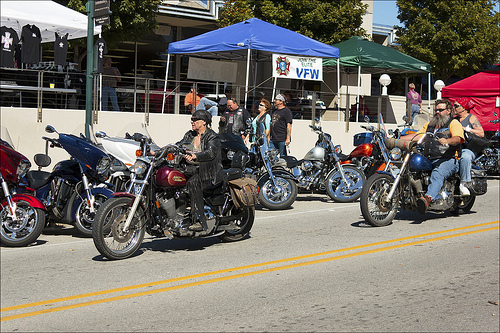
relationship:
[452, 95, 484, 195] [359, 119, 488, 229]
man on bike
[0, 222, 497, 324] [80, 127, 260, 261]
line on bike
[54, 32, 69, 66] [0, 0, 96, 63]
shirt hanging tent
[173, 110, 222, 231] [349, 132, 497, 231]
guy riding bike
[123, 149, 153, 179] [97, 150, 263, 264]
light in bike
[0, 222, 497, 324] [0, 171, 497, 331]
line in road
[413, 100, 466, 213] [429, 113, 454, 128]
guy with a beard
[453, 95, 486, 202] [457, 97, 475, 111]
woman wearing red bandanna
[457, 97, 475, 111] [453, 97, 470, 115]
red bandanna on head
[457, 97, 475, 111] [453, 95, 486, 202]
red bandanna on woman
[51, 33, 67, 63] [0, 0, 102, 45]
shirt hanging canopy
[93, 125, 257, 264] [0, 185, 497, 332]
bike parked pavement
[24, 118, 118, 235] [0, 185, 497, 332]
bike parked pavement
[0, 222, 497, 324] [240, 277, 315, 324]
line on pavement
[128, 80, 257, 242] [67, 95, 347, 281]
guy riding bike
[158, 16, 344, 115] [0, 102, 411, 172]
canopy on sidewalk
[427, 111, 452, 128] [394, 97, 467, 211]
beard of guy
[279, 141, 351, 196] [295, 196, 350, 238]
motorcycle parked sidewalk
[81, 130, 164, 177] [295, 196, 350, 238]
motorcycle parked sidewalk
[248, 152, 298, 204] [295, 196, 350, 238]
motorcycle parked sidewalk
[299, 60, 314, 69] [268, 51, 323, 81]
word in banner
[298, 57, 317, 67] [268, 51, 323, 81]
word in banner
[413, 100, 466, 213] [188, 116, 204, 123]
guy wearing sunglasses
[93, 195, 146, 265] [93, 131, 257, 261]
wheel of bike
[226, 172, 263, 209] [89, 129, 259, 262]
bag attached to motorcycle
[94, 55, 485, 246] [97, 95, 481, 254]
group of people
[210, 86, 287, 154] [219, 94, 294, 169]
people are walking